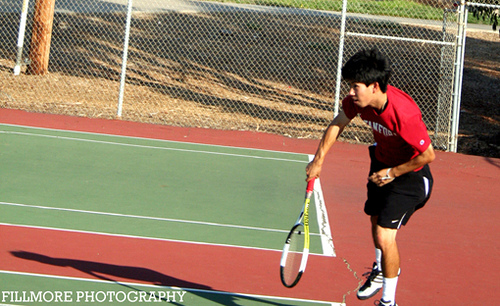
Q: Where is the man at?
A: On a green tennis court.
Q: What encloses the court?
A: A chain linked fence.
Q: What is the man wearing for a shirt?
A: A red Polo shirt.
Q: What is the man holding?
A: A tennis racket.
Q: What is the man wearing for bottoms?
A: Black shorts.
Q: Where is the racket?
A: Perpendicular to the ground.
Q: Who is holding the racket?
A: The boy.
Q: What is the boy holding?
A: The racket.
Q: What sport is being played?
A: Tennis.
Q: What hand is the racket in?
A: Right.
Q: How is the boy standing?
A: Slouched over.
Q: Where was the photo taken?
A: Tennis court.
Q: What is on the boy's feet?
A: Sneakers.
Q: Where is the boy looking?
A: Straight ahead.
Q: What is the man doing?
A: Playing tennis.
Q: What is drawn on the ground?
A: Lines.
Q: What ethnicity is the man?
A: Asian.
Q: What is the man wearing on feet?
A: Shoes.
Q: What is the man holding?
A: Racket.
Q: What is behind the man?
A: Fence.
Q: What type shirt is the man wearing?
A: Red.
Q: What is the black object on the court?
A: Shadow.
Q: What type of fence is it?
A: Chain link.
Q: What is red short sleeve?
A: A cotton t-shirt.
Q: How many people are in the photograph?
A: One.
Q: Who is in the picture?
A: A man.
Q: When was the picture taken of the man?
A: Daytime.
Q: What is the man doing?
A: Playing tennis.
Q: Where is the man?
A: Tennis court.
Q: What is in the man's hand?
A: Tennis racket.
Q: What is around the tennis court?
A: A fence.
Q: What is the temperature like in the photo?
A: Warm.